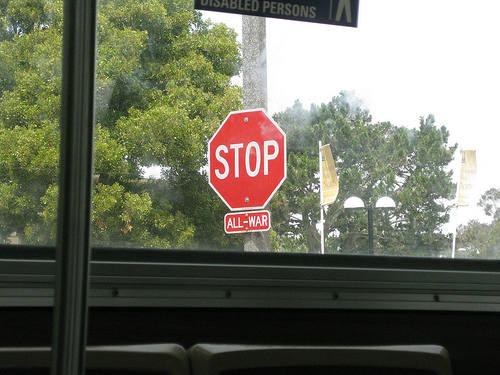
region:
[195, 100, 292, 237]
The sign is red.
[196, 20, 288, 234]
Two signs on the pole.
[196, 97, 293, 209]
The sign is octagon.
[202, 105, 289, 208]
The sign says stop.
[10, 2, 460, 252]
The trees are green.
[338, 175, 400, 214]
Lamp shade is white.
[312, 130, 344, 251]
Flag hanging on the pole.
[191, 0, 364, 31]
Sign on bus window.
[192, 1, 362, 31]
The text is white.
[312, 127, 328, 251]
The pole is white.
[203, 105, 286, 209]
Red and white stop sign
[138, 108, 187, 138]
Small section of green tree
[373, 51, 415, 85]
A clear overcast sky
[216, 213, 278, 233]
Sign that reads All-War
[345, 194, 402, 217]
Two black and white street lights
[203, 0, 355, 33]
Sign that reads Disabled Persons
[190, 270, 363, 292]
Gray rail that is inside the vehicle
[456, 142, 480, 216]
Sign that is located outside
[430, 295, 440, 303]
Screw that is on the far right of the picture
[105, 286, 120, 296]
Screw that is on the far left of the picture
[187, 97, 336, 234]
sign stop is red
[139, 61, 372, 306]
sign stop is red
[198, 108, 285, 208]
sign says stop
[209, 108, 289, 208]
sign is shape of octagon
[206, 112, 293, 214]
sign is red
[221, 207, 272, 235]
sign says "all War"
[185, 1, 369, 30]
sign is rectangle and blue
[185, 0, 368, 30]
sign says disabled persons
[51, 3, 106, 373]
pole on the bus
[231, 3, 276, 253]
sign on a pole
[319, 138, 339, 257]
banner on pole is yellow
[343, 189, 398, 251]
street light on black pole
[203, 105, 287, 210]
a stop sign is on a pole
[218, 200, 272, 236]
a small sign is below the stop sign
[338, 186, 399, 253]
a lamp post is on the side of the road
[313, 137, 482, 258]
flags are flying on the side of the road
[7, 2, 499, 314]
a window from inside a bus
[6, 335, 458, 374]
plastic chair backs on the bus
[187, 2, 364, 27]
a sign on the window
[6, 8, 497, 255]
trees are outside the bus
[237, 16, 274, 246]
a pole where the signs are posted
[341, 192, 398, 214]
two white globes are on the post